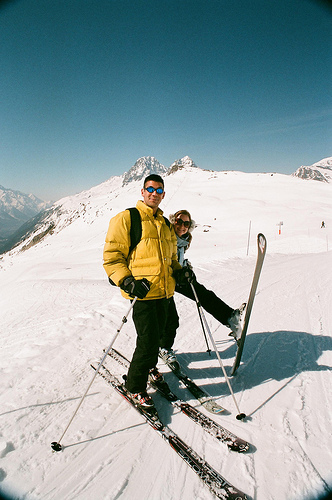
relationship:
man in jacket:
[103, 174, 196, 407] [102, 200, 181, 301]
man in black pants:
[103, 174, 196, 407] [127, 296, 179, 395]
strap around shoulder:
[124, 211, 148, 246] [117, 206, 153, 226]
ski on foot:
[224, 224, 272, 381] [223, 298, 248, 343]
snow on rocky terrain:
[0, 156, 331, 498] [0, 144, 331, 264]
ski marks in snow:
[75, 308, 287, 498] [0, 156, 331, 498]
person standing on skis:
[160, 205, 243, 364] [162, 233, 268, 416]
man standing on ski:
[103, 174, 196, 407] [91, 345, 251, 500]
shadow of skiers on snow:
[180, 325, 330, 405] [257, 417, 308, 468]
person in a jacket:
[158, 210, 247, 363] [172, 230, 190, 273]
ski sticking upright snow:
[230, 234, 266, 376] [268, 450, 311, 482]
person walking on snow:
[321, 220, 325, 228] [0, 156, 331, 498]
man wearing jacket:
[103, 174, 179, 407] [92, 190, 187, 297]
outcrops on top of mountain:
[111, 133, 220, 206] [92, 121, 299, 207]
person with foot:
[158, 210, 247, 363] [228, 302, 247, 345]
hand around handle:
[127, 276, 148, 303] [45, 277, 149, 452]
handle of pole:
[45, 277, 149, 452] [38, 255, 192, 459]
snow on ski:
[0, 156, 331, 498] [97, 344, 256, 497]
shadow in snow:
[148, 330, 332, 424] [10, 394, 109, 434]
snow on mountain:
[0, 156, 331, 498] [0, 152, 329, 249]